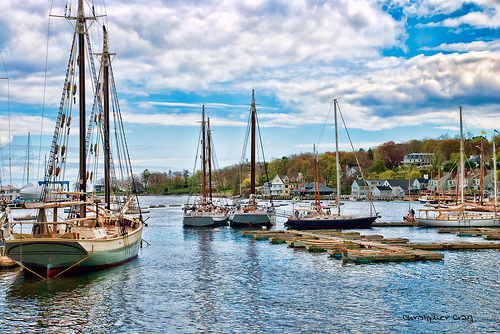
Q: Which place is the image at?
A: It is at the lake.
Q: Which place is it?
A: It is a lake.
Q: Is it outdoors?
A: Yes, it is outdoors.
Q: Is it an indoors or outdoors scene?
A: It is outdoors.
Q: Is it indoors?
A: No, it is outdoors.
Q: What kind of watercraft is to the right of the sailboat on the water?
A: The watercraft is boats.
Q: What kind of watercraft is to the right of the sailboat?
A: The watercraft is boats.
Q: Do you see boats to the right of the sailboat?
A: Yes, there are boats to the right of the sailboat.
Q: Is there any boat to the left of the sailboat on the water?
A: No, the boats are to the right of the sailboat.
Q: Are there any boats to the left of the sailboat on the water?
A: No, the boats are to the right of the sailboat.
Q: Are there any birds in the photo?
A: No, there are no birds.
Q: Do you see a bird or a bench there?
A: No, there are no birds or benches.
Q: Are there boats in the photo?
A: Yes, there is a boat.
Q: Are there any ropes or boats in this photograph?
A: Yes, there is a boat.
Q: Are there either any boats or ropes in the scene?
A: Yes, there is a boat.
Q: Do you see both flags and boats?
A: No, there is a boat but no flags.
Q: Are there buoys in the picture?
A: No, there are no buoys.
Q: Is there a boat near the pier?
A: Yes, there is a boat near the pier.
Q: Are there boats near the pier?
A: Yes, there is a boat near the pier.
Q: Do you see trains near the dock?
A: No, there is a boat near the dock.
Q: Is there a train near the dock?
A: No, there is a boat near the dock.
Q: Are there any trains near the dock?
A: No, there is a boat near the dock.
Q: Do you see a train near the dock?
A: No, there is a boat near the dock.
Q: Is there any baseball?
A: No, there are no baseballs.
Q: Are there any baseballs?
A: No, there are no baseballs.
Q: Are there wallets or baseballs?
A: No, there are no baseballs or wallets.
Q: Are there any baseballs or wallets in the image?
A: No, there are no baseballs or wallets.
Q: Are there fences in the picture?
A: No, there are no fences.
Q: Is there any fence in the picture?
A: No, there are no fences.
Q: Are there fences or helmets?
A: No, there are no fences or helmets.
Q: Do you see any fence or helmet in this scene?
A: No, there are no fences or helmets.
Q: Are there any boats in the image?
A: Yes, there is a boat.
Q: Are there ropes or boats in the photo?
A: Yes, there is a boat.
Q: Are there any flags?
A: No, there are no flags.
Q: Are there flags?
A: No, there are no flags.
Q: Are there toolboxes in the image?
A: No, there are no toolboxes.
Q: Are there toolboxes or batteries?
A: No, there are no toolboxes or batteries.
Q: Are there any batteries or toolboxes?
A: No, there are no toolboxes or batteries.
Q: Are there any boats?
A: Yes, there is a boat.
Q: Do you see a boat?
A: Yes, there is a boat.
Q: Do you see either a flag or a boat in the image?
A: Yes, there is a boat.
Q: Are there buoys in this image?
A: No, there are no buoys.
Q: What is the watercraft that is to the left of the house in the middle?
A: The watercraft is a boat.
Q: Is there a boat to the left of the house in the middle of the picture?
A: Yes, there is a boat to the left of the house.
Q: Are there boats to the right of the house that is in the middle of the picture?
A: No, the boat is to the left of the house.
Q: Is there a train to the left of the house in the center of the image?
A: No, there is a boat to the left of the house.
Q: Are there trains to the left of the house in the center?
A: No, there is a boat to the left of the house.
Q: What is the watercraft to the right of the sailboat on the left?
A: The watercraft is a boat.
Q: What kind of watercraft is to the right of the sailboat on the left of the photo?
A: The watercraft is a boat.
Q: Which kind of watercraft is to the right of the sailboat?
A: The watercraft is a boat.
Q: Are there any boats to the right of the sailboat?
A: Yes, there is a boat to the right of the sailboat.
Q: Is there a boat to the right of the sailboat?
A: Yes, there is a boat to the right of the sailboat.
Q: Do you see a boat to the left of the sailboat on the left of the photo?
A: No, the boat is to the right of the sailboat.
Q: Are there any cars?
A: No, there are no cars.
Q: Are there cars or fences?
A: No, there are no cars or fences.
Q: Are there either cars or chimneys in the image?
A: No, there are no cars or chimneys.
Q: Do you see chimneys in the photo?
A: No, there are no chimneys.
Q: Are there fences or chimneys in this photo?
A: No, there are no chimneys or fences.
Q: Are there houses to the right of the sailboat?
A: Yes, there is a house to the right of the sailboat.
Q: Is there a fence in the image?
A: No, there are no fences.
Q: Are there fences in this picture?
A: No, there are no fences.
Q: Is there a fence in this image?
A: No, there are no fences.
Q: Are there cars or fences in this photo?
A: No, there are no fences or cars.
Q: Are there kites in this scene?
A: No, there are no kites.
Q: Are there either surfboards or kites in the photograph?
A: No, there are no kites or surfboards.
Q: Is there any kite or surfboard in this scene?
A: No, there are no kites or surfboards.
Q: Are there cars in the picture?
A: No, there are no cars.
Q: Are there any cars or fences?
A: No, there are no cars or fences.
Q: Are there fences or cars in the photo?
A: No, there are no cars or fences.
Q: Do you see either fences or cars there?
A: No, there are no cars or fences.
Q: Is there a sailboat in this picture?
A: Yes, there is a sailboat.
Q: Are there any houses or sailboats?
A: Yes, there is a sailboat.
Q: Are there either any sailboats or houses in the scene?
A: Yes, there is a sailboat.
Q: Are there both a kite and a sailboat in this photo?
A: No, there is a sailboat but no kites.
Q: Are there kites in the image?
A: No, there are no kites.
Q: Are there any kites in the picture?
A: No, there are no kites.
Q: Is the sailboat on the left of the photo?
A: Yes, the sailboat is on the left of the image.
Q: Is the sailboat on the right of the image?
A: No, the sailboat is on the left of the image.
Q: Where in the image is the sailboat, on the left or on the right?
A: The sailboat is on the left of the image.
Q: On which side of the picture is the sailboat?
A: The sailboat is on the left of the image.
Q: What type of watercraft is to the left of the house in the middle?
A: The watercraft is a sailboat.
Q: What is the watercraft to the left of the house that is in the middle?
A: The watercraft is a sailboat.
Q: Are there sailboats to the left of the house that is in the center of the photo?
A: Yes, there is a sailboat to the left of the house.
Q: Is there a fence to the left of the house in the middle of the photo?
A: No, there is a sailboat to the left of the house.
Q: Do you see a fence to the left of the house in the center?
A: No, there is a sailboat to the left of the house.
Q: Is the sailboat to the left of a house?
A: Yes, the sailboat is to the left of a house.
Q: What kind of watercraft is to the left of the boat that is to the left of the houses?
A: The watercraft is a sailboat.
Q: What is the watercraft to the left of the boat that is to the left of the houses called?
A: The watercraft is a sailboat.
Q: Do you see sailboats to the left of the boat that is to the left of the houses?
A: Yes, there is a sailboat to the left of the boat.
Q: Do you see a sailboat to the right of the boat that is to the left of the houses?
A: No, the sailboat is to the left of the boat.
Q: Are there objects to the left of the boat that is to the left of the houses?
A: No, there is a sailboat to the left of the boat.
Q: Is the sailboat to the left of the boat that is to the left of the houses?
A: Yes, the sailboat is to the left of the boat.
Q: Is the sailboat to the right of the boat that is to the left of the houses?
A: No, the sailboat is to the left of the boat.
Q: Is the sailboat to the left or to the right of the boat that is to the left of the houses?
A: The sailboat is to the left of the boat.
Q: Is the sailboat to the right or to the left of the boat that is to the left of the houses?
A: The sailboat is to the left of the boat.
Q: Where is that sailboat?
A: The sailboat is on the water.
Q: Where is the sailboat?
A: The sailboat is on the water.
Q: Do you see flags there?
A: No, there are no flags.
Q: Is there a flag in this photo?
A: No, there are no flags.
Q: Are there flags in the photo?
A: No, there are no flags.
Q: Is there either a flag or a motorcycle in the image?
A: No, there are no flags or motorcycles.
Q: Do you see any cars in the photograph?
A: No, there are no cars.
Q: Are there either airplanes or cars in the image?
A: No, there are no cars or airplanes.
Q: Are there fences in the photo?
A: No, there are no fences.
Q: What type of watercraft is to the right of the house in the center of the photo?
A: The watercraft is boats.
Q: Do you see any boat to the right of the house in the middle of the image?
A: Yes, there are boats to the right of the house.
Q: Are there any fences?
A: No, there are no fences.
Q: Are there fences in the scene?
A: No, there are no fences.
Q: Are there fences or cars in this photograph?
A: No, there are no fences or cars.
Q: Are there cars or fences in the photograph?
A: No, there are no fences or cars.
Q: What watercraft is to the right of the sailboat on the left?
A: The watercraft is boats.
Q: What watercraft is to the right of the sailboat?
A: The watercraft is boats.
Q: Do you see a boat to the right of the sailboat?
A: Yes, there are boats to the right of the sailboat.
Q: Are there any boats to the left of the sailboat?
A: No, the boats are to the right of the sailboat.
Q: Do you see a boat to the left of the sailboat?
A: No, the boats are to the right of the sailboat.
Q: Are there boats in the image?
A: Yes, there is a boat.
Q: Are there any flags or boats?
A: Yes, there is a boat.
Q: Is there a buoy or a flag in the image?
A: No, there are no flags or buoys.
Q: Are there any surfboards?
A: No, there are no surfboards.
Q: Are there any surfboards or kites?
A: No, there are no surfboards or kites.